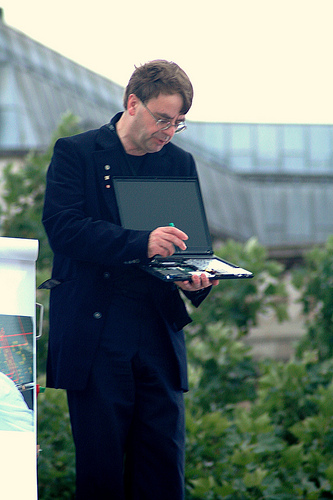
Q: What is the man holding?
A: Computer.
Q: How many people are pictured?
A: 1.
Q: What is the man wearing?
A: Suit.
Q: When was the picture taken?
A: Daytime.